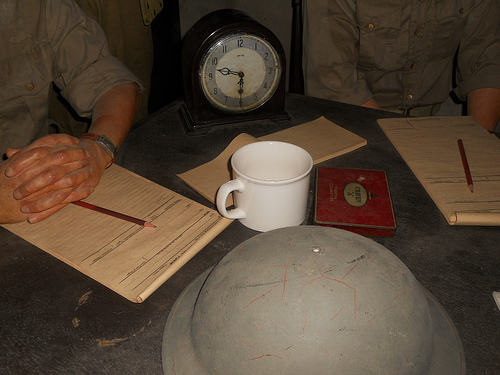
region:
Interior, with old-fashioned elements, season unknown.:
[2, 2, 497, 372]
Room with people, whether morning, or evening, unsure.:
[1, 0, 491, 370]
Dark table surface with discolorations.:
[15, 280, 117, 365]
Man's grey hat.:
[160, 230, 470, 370]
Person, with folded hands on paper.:
[0, 5, 115, 220]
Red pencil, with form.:
[81, 165, 196, 295]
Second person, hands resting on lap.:
[311, 2, 496, 113]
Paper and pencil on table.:
[385, 110, 497, 217]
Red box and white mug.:
[216, 150, 391, 230]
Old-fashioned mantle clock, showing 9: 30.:
[167, 8, 283, 143]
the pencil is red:
[46, 170, 203, 267]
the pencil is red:
[65, 186, 179, 250]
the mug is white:
[169, 115, 317, 285]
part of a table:
[442, 191, 456, 213]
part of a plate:
[354, 283, 368, 296]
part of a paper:
[143, 295, 150, 304]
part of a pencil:
[146, 215, 153, 236]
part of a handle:
[217, 190, 227, 207]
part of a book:
[363, 218, 375, 245]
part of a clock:
[248, 51, 263, 98]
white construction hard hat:
[150, 214, 477, 374]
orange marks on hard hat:
[242, 245, 367, 366]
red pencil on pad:
[67, 195, 161, 237]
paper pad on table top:
[2, 135, 232, 309]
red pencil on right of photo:
[450, 135, 479, 200]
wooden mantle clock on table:
[167, 3, 304, 134]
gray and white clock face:
[194, 33, 284, 118]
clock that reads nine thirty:
[189, 26, 289, 121]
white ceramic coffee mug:
[207, 138, 320, 237]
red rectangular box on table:
[309, 158, 402, 248]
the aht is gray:
[298, 264, 343, 304]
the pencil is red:
[87, 199, 117, 220]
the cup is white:
[253, 186, 279, 214]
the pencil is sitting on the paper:
[453, 132, 470, 172]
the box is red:
[334, 183, 360, 212]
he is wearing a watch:
[81, 122, 122, 168]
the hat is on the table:
[152, 313, 199, 353]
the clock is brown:
[191, 92, 210, 126]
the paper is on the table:
[435, 189, 467, 247]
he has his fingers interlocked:
[13, 143, 96, 211]